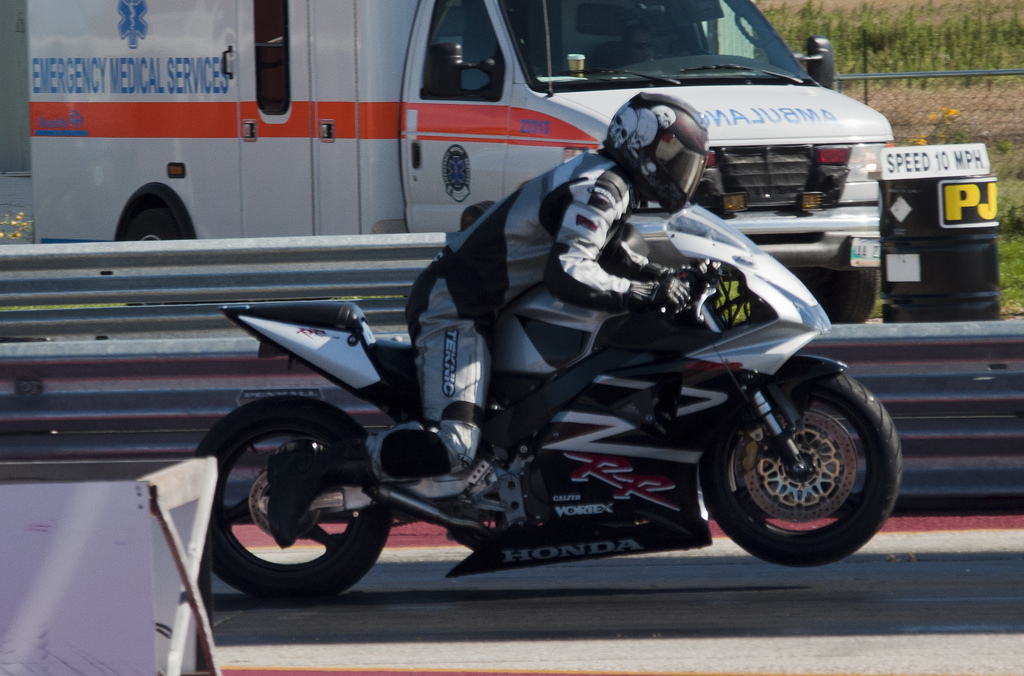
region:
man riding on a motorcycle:
[192, 91, 904, 601]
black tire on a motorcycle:
[192, 393, 392, 606]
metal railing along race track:
[6, 318, 1022, 519]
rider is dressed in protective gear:
[266, 91, 706, 548]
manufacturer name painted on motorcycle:
[495, 529, 647, 575]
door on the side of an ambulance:
[227, 2, 319, 243]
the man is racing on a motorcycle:
[187, 92, 909, 601]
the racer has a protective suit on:
[356, 165, 638, 514]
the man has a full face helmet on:
[585, 94, 710, 213]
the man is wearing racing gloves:
[631, 268, 692, 317]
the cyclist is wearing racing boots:
[250, 439, 377, 551]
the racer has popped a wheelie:
[185, 91, 907, 608]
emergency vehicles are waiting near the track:
[16, 4, 890, 267]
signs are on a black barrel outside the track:
[875, 142, 1003, 333]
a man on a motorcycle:
[316, 70, 708, 504]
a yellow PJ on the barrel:
[935, 174, 1002, 235]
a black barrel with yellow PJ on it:
[869, 160, 1006, 348]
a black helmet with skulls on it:
[604, 94, 718, 225]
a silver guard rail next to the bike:
[21, 278, 1023, 504]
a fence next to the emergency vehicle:
[857, 51, 1022, 189]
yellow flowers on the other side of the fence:
[915, 94, 991, 153]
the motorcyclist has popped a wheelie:
[195, 98, 907, 612]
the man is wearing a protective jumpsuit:
[362, 160, 654, 494]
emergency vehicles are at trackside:
[15, 9, 902, 253]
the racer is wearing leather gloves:
[623, 247, 707, 333]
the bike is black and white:
[190, 220, 909, 620]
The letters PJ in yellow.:
[945, 185, 993, 224]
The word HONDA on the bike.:
[501, 544, 638, 561]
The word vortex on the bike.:
[555, 494, 619, 523]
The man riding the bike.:
[207, 80, 913, 672]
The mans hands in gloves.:
[639, 251, 691, 318]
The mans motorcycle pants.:
[352, 276, 485, 505]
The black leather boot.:
[273, 433, 360, 538]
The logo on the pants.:
[434, 318, 461, 408]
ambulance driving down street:
[16, 3, 898, 327]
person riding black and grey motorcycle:
[193, 86, 920, 622]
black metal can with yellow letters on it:
[866, 173, 1013, 330]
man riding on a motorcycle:
[198, 87, 919, 607]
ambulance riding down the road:
[7, 7, 932, 324]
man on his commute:
[127, 83, 925, 600]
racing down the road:
[193, 80, 911, 611]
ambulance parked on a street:
[19, 7, 955, 362]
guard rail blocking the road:
[0, 232, 1010, 523]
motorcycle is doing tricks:
[196, 185, 915, 606]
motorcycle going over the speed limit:
[175, 194, 923, 622]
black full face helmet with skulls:
[599, 90, 708, 218]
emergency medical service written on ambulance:
[35, 38, 236, 103]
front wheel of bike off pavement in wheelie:
[702, 364, 912, 564]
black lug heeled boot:
[257, 441, 363, 550]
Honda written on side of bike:
[490, 526, 642, 577]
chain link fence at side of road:
[863, 44, 1022, 196]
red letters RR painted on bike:
[550, 444, 681, 520]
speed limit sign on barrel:
[866, 130, 1007, 187]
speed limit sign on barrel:
[855, 123, 1002, 181]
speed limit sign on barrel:
[867, 135, 1000, 190]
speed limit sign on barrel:
[861, 135, 994, 187]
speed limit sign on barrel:
[873, 136, 994, 187]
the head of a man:
[595, 91, 717, 234]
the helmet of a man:
[626, 96, 706, 182]